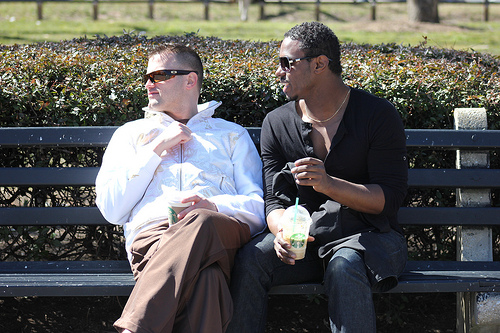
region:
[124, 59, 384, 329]
two popl are seatd on a bench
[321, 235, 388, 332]
the pants are black in color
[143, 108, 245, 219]
the jacket is white in color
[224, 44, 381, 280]
man is drinking a coffe in the tin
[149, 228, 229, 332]
pants are brown in clor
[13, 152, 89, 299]
the baench is wooden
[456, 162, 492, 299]
the bench is hel by a concrete pillar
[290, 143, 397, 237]
the shirt is black incolor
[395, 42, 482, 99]
the plants are beside the bench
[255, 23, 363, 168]
thweman is wearingsunglases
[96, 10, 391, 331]
Both are wearing sunglasses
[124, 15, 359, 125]
They're looking at the same thing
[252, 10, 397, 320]
He's drinking Starbuck's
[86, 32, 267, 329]
Man in white jacket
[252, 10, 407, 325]
Man wearing a black shirt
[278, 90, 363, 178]
A very deep V-neck shirt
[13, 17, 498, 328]
Sitting on a bench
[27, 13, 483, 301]
Bushes are behind them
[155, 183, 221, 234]
Holding a Starbuck's cup in his hand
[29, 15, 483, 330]
Looks to be a sunny day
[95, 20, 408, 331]
Two men sitting on a bench.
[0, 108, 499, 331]
A bench made from concert and wood.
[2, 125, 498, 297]
Specks of white paint can be seen on the wood.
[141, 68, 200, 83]
A pair of sunglasses on the man's face.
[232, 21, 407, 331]
The man is holding a Starbucks coffee.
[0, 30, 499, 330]
A hedge is behind the bench.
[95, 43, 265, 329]
The man is wearing a white jacket and brown pants.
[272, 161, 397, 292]
A black jacket in the man's lap.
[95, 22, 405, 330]
The two men are both looking to the right.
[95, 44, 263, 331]
The man is sitting with his legs crossed.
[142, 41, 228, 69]
man has short hair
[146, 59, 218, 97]
man has brown glasses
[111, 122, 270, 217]
man has white jacket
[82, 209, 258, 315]
man has brown pants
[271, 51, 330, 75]
man has black glasses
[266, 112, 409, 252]
man has black shirt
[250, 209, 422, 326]
man has blue pants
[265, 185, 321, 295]
man holds frozen drink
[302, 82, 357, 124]
man is wearing necklace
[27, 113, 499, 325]
men on blue bench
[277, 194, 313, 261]
Half empty Starbucks drink.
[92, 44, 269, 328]
Caucasian man wearing sunglasses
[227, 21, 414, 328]
African American man wearing sunglasses.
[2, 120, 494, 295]
Darkly painted, stone bench.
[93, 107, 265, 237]
White zip up over shirt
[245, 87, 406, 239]
Black button up, long sleeved shirt.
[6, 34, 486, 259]
Neatly trimmed shrubbery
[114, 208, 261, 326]
Brown khaki pants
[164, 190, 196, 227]
Nearly full Starbuck's beverage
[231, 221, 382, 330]
Dark wash jean pants